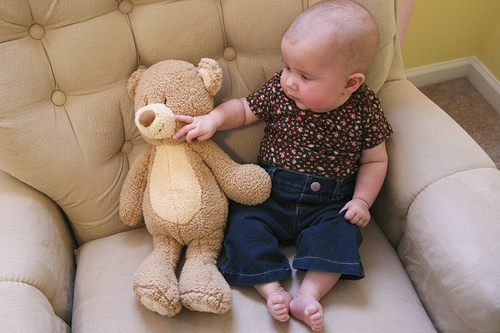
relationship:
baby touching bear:
[172, 1, 396, 332] [120, 57, 271, 314]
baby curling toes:
[172, 1, 396, 332] [272, 296, 323, 330]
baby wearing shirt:
[172, 1, 396, 332] [247, 71, 392, 180]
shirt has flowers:
[247, 71, 392, 180] [295, 123, 303, 133]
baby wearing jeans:
[172, 1, 396, 332] [223, 159, 367, 279]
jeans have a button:
[223, 159, 367, 279] [311, 180, 321, 193]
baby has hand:
[172, 1, 396, 332] [174, 115, 219, 141]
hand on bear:
[174, 115, 219, 141] [120, 57, 271, 314]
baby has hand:
[172, 1, 396, 332] [339, 199, 369, 228]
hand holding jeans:
[174, 115, 219, 141] [223, 159, 367, 279]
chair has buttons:
[0, 0, 498, 330] [30, 2, 241, 159]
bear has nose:
[120, 57, 271, 314] [139, 109, 155, 126]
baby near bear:
[172, 1, 396, 332] [120, 57, 271, 314]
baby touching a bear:
[172, 1, 396, 332] [120, 57, 271, 314]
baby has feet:
[172, 1, 396, 332] [268, 292, 322, 332]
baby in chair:
[172, 1, 396, 332] [0, 0, 498, 330]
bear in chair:
[120, 57, 271, 314] [0, 0, 498, 330]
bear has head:
[120, 57, 271, 314] [128, 58, 222, 145]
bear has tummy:
[120, 57, 271, 314] [142, 143, 225, 240]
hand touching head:
[174, 115, 219, 141] [128, 58, 222, 145]